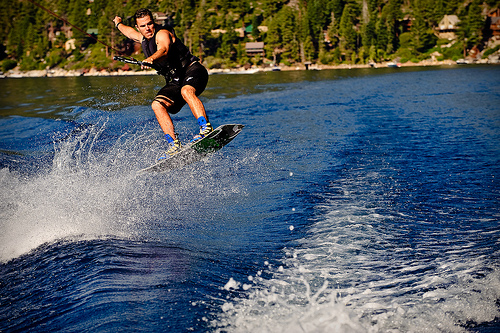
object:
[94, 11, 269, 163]
man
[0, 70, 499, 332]
water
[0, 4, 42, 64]
trees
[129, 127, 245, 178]
board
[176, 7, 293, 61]
houses